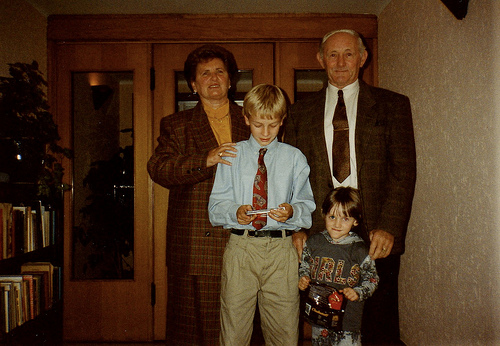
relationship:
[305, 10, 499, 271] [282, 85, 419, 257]
man wears jacket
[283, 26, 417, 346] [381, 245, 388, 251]
man wears ring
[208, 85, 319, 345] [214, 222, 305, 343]
boy wears pants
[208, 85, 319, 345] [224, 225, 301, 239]
boy wears dark belt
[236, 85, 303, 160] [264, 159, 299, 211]
boy wears shirt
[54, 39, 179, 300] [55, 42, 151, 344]
glass on door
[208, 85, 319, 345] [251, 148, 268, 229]
boy wears tie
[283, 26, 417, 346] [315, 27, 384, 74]
man has grey hair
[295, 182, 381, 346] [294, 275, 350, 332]
child has toy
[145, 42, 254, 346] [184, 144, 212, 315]
woman wears tie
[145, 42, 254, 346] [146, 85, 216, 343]
woman wears jacket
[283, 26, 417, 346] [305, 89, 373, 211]
man wears tie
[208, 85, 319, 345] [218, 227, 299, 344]
boy wears pants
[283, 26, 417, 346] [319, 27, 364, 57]
man has gray hair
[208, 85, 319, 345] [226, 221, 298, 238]
boy has black belt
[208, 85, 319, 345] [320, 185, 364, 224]
boy has hair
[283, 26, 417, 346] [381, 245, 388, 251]
man has ring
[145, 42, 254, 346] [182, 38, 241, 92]
woman has hair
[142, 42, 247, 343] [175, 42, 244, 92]
woman has hair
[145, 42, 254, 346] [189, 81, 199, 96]
woman wearing earrings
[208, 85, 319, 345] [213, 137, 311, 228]
boy wearing shirt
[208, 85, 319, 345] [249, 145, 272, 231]
boy wearing tie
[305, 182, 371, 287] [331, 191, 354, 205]
child with hair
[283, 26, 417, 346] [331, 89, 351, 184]
man wearing tie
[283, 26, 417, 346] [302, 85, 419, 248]
man wearing jacket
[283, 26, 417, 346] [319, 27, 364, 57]
man with gray hair